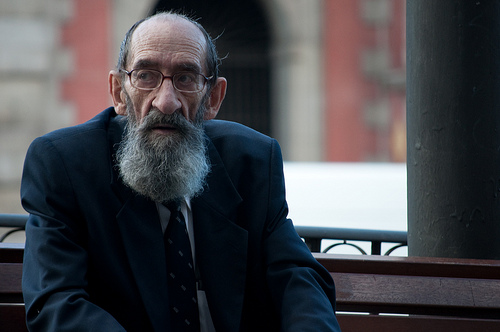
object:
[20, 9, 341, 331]
man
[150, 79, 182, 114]
nose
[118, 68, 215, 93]
eyeglasses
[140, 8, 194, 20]
hair line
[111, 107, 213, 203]
moustache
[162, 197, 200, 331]
necktie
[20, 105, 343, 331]
suit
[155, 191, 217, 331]
shirt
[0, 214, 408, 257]
railing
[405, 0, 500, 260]
support post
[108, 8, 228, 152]
head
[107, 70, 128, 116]
ear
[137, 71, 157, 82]
eye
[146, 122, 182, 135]
mouth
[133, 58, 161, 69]
eyebrow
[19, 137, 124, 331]
arm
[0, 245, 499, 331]
bench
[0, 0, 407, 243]
building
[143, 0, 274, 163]
entryway